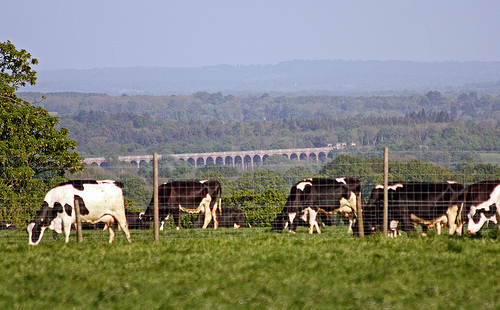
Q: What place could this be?
A: It is a field.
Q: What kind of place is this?
A: It is a field.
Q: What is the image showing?
A: It is showing a field.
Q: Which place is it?
A: It is a field.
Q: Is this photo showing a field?
A: Yes, it is showing a field.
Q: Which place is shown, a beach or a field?
A: It is a field.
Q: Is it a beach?
A: No, it is a field.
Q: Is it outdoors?
A: Yes, it is outdoors.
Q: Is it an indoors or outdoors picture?
A: It is outdoors.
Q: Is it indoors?
A: No, it is outdoors.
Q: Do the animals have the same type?
A: Yes, all the animals are cows.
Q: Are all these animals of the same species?
A: Yes, all the animals are cows.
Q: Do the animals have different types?
A: No, all the animals are cows.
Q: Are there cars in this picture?
A: No, there are no cars.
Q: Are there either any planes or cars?
A: No, there are no cars or planes.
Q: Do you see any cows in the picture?
A: Yes, there are cows.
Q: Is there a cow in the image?
A: Yes, there are cows.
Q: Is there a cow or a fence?
A: Yes, there are cows.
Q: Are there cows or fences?
A: Yes, there are cows.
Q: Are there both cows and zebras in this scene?
A: No, there are cows but no zebras.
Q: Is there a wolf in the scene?
A: No, there are no wolves.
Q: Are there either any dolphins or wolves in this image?
A: No, there are no wolves or dolphins.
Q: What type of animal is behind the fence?
A: The animals are cows.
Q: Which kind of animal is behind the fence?
A: The animals are cows.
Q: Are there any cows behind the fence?
A: Yes, there are cows behind the fence.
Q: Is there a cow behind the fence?
A: Yes, there are cows behind the fence.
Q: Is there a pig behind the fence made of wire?
A: No, there are cows behind the fence.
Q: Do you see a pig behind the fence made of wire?
A: No, there are cows behind the fence.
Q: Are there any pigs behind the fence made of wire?
A: No, there are cows behind the fence.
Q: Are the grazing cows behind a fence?
A: Yes, the cows are behind a fence.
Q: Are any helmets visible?
A: No, there are no helmets.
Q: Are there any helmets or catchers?
A: No, there are no helmets or catchers.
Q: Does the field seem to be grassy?
A: Yes, the field is grassy.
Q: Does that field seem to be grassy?
A: Yes, the field is grassy.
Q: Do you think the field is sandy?
A: No, the field is grassy.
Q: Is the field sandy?
A: No, the field is grassy.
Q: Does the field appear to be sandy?
A: No, the field is grassy.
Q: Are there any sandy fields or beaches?
A: No, there is a field but it is grassy.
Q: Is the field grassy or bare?
A: The field is grassy.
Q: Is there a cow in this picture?
A: Yes, there is a cow.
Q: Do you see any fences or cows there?
A: Yes, there is a cow.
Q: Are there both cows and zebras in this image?
A: No, there is a cow but no zebras.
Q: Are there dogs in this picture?
A: No, there are no dogs.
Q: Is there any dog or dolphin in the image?
A: No, there are no dogs or dolphins.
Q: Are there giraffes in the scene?
A: No, there are no giraffes.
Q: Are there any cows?
A: Yes, there is a cow.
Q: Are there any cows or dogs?
A: Yes, there is a cow.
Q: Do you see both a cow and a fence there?
A: Yes, there are both a cow and a fence.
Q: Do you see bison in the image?
A: No, there are no bison.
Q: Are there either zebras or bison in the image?
A: No, there are no bison or zebras.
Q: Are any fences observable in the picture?
A: Yes, there is a fence.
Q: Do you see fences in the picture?
A: Yes, there is a fence.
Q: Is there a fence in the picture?
A: Yes, there is a fence.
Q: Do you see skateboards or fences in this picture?
A: Yes, there is a fence.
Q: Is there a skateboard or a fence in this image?
A: Yes, there is a fence.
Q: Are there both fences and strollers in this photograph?
A: No, there is a fence but no strollers.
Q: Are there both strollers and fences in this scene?
A: No, there is a fence but no strollers.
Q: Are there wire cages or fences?
A: Yes, there is a wire fence.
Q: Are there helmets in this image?
A: No, there are no helmets.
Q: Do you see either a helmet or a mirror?
A: No, there are no helmets or mirrors.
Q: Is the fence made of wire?
A: Yes, the fence is made of wire.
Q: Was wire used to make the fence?
A: Yes, the fence is made of wire.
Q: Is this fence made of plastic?
A: No, the fence is made of wire.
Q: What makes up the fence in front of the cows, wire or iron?
A: The fence is made of wire.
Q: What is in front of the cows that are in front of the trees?
A: The fence is in front of the cows.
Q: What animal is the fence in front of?
A: The fence is in front of the cows.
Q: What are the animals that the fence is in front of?
A: The animals are cows.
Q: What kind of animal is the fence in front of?
A: The fence is in front of the cows.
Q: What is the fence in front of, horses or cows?
A: The fence is in front of cows.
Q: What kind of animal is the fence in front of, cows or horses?
A: The fence is in front of cows.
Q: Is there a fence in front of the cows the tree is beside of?
A: Yes, there is a fence in front of the cows.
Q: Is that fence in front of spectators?
A: No, the fence is in front of the cows.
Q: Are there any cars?
A: No, there are no cars.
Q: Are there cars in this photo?
A: No, there are no cars.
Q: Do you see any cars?
A: No, there are no cars.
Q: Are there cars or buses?
A: No, there are no cars or buses.